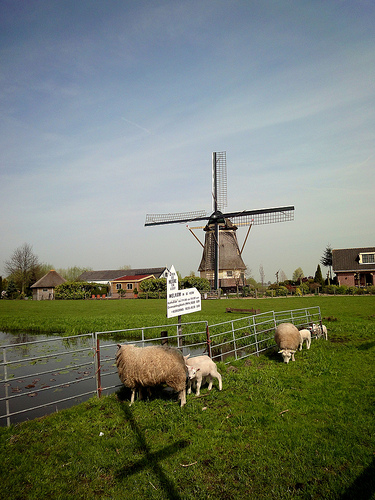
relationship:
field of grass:
[229, 391, 337, 460] [0, 293, 375, 500]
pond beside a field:
[11, 335, 106, 401] [4, 295, 332, 488]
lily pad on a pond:
[57, 366, 72, 375] [1, 327, 221, 432]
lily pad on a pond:
[47, 355, 63, 365] [1, 327, 221, 432]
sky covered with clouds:
[44, 26, 130, 95] [88, 112, 172, 169]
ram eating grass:
[115, 341, 189, 407] [0, 293, 375, 500]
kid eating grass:
[185, 355, 222, 397] [0, 293, 375, 500]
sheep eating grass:
[271, 322, 304, 367] [0, 293, 375, 500]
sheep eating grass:
[299, 329, 313, 353] [0, 293, 375, 500]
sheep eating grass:
[319, 323, 331, 338] [0, 293, 375, 500]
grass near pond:
[0, 293, 375, 500] [2, 327, 203, 424]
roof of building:
[331, 246, 373, 271] [109, 273, 154, 294]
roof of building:
[112, 273, 150, 283] [331, 249, 373, 289]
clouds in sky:
[15, 91, 289, 238] [145, 30, 295, 96]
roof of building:
[331, 246, 375, 271] [331, 245, 374, 288]